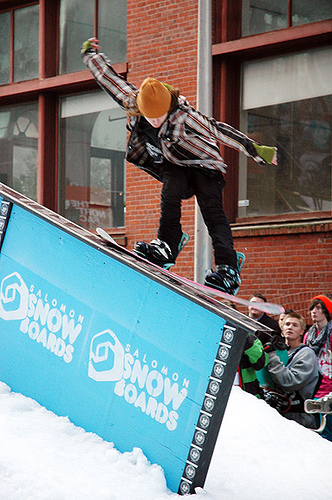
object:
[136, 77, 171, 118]
beanie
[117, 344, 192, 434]
lettering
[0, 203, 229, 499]
sign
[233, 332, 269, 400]
sweater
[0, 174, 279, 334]
rail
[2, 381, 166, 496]
snow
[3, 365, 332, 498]
ground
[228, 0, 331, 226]
window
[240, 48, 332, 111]
curtains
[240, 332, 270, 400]
stripes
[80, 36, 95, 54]
gloves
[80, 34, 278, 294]
boy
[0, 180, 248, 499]
ramp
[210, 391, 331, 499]
snow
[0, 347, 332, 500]
hill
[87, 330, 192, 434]
brand name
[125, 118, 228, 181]
jacket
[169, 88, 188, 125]
hood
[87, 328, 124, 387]
logo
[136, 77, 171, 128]
head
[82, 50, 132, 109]
arm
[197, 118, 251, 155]
arm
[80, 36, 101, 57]
hand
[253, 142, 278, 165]
hand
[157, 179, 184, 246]
leg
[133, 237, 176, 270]
foot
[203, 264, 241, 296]
foot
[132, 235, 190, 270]
boot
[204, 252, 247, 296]
boot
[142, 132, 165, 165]
shirt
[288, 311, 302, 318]
hair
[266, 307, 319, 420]
man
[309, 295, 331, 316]
hat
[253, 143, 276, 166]
glove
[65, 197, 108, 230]
sign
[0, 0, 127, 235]
window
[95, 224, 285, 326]
snowboard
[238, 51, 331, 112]
blind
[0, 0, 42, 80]
pane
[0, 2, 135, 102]
top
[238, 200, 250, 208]
sticker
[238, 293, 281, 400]
person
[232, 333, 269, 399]
shirt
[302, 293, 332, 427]
kid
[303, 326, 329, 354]
shirt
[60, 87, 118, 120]
blind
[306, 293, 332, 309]
head warmer